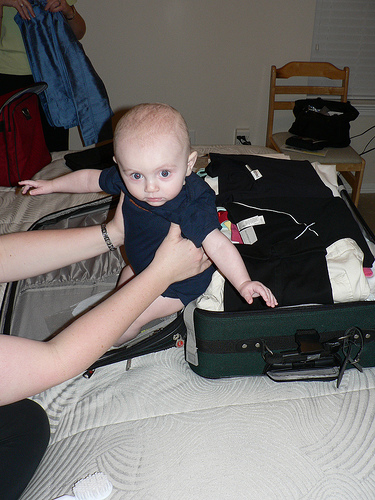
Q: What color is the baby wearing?
A: Blue.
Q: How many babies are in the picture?
A: One.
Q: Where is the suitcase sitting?
A: On bed.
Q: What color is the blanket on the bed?
A: White.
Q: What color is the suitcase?
A: Green.